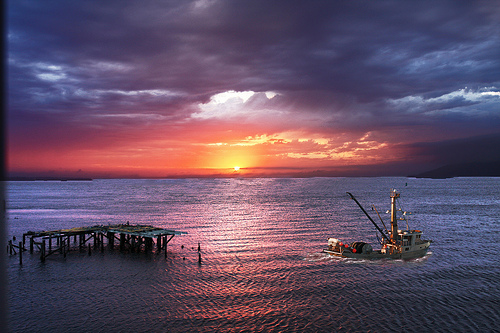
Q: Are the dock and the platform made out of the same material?
A: No, the dock is made of wood and the platform is made of metal.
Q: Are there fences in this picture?
A: No, there are no fences.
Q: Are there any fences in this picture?
A: No, there are no fences.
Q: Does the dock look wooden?
A: Yes, the dock is wooden.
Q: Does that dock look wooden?
A: Yes, the dock is wooden.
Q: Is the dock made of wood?
A: Yes, the dock is made of wood.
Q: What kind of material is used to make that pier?
A: The pier is made of wood.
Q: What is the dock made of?
A: The pier is made of wood.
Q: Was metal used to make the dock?
A: No, the dock is made of wood.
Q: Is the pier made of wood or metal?
A: The pier is made of wood.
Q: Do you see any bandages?
A: No, there are no bandages.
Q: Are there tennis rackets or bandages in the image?
A: No, there are no bandages or tennis rackets.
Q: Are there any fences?
A: No, there are no fences.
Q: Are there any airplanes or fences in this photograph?
A: No, there are no fences or airplanes.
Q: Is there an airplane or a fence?
A: No, there are no fences or airplanes.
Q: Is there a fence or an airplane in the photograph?
A: No, there are no fences or airplanes.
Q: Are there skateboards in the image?
A: No, there are no skateboards.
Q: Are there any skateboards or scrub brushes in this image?
A: No, there are no skateboards or scrub brushes.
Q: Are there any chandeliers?
A: No, there are no chandeliers.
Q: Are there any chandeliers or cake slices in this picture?
A: No, there are no chandeliers or cake slices.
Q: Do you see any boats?
A: Yes, there is a boat.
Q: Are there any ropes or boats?
A: Yes, there is a boat.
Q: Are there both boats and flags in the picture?
A: No, there is a boat but no flags.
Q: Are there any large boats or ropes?
A: Yes, there is a large boat.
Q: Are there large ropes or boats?
A: Yes, there is a large boat.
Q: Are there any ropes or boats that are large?
A: Yes, the boat is large.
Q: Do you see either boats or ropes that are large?
A: Yes, the boat is large.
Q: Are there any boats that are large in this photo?
A: Yes, there is a large boat.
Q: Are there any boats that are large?
A: Yes, there is a boat that is large.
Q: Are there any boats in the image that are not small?
A: Yes, there is a large boat.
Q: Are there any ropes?
A: No, there are no ropes.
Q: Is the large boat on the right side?
A: Yes, the boat is on the right of the image.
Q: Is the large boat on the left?
A: No, the boat is on the right of the image.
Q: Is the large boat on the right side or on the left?
A: The boat is on the right of the image.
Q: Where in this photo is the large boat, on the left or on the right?
A: The boat is on the right of the image.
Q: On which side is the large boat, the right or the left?
A: The boat is on the right of the image.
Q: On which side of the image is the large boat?
A: The boat is on the right of the image.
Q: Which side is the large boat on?
A: The boat is on the right of the image.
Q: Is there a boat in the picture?
A: Yes, there is a boat.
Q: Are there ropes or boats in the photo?
A: Yes, there is a boat.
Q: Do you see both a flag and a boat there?
A: No, there is a boat but no flags.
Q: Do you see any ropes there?
A: No, there are no ropes.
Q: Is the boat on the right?
A: Yes, the boat is on the right of the image.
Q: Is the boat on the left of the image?
A: No, the boat is on the right of the image.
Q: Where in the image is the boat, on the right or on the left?
A: The boat is on the right of the image.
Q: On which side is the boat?
A: The boat is on the right of the image.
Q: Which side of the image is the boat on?
A: The boat is on the right of the image.